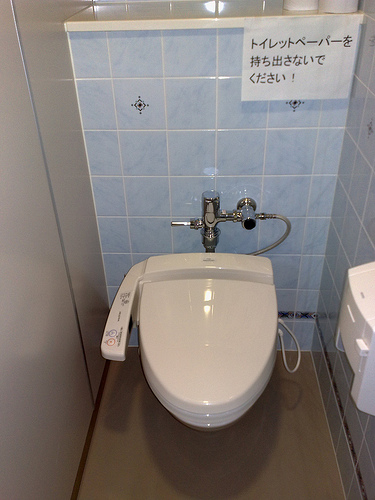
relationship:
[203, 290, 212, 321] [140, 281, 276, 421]
light reflecting seat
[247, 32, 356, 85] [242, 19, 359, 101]
letters on instructions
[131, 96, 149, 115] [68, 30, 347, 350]
accent on tiles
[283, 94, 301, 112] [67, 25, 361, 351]
accent on tile wall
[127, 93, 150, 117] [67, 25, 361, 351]
accent on tile wall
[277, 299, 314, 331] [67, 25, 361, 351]
accent on tile wall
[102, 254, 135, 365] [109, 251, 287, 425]
side bar on toilet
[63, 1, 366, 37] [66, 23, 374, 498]
white shelf on wall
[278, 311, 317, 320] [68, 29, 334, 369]
accent on tile wall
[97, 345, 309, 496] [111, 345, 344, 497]
shadow on floor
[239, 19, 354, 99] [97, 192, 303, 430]
instructions on toilet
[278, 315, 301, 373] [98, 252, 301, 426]
hose attached to toilet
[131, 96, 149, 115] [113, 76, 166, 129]
accent on tile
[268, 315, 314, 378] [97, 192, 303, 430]
hose on toilet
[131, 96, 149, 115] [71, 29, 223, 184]
accent on wall